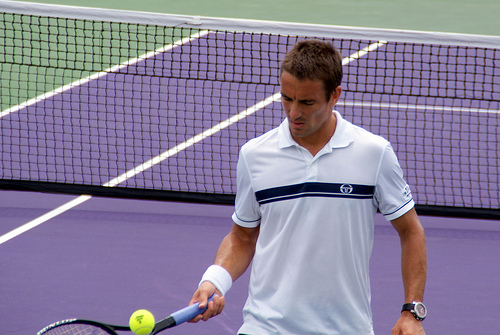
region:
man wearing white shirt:
[148, 22, 445, 328]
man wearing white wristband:
[175, 21, 434, 333]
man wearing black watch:
[131, 22, 462, 329]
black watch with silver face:
[397, 289, 439, 324]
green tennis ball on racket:
[120, 307, 159, 333]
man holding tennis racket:
[33, 25, 438, 332]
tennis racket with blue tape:
[45, 302, 220, 334]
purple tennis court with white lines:
[12, 27, 481, 314]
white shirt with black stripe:
[237, 122, 427, 328]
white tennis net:
[5, 7, 497, 206]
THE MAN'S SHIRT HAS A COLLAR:
[276, 108, 354, 173]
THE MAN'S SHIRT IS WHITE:
[218, 111, 401, 332]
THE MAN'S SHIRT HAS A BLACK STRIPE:
[248, 175, 384, 221]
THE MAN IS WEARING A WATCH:
[400, 298, 434, 325]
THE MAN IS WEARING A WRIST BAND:
[187, 261, 237, 304]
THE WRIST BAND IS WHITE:
[191, 256, 238, 301]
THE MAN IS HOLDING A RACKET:
[33, 287, 229, 334]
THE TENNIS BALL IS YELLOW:
[124, 300, 171, 334]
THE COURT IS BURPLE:
[3, 23, 495, 333]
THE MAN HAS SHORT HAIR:
[276, 37, 350, 111]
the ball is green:
[66, 233, 196, 329]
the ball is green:
[66, 262, 130, 327]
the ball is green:
[95, 255, 165, 330]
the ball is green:
[129, 287, 169, 326]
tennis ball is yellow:
[76, 311, 173, 332]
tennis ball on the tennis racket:
[48, 305, 201, 331]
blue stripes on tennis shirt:
[233, 166, 420, 235]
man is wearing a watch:
[385, 287, 457, 314]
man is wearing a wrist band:
[199, 244, 249, 294]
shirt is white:
[239, 154, 388, 309]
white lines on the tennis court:
[84, 43, 249, 158]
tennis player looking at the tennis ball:
[272, 67, 359, 177]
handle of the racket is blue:
[170, 277, 247, 325]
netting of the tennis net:
[73, 60, 237, 151]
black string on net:
[122, 43, 215, 128]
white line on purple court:
[17, 192, 67, 239]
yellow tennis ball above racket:
[121, 305, 162, 333]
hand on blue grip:
[173, 286, 235, 326]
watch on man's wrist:
[395, 296, 435, 326]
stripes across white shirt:
[247, 178, 387, 217]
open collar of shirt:
[277, 128, 349, 162]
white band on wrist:
[195, 258, 239, 300]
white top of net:
[390, 22, 478, 57]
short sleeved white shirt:
[225, 125, 417, 281]